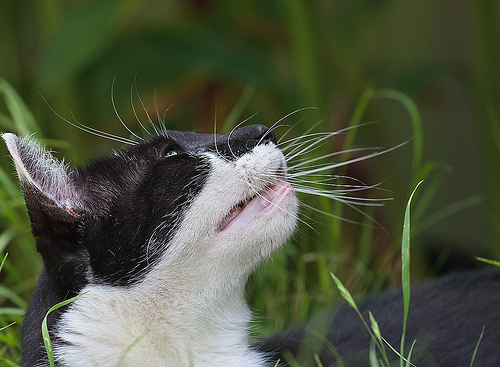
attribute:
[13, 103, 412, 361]
cat — lying, looking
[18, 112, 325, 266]
cat fur — white 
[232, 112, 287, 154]
nose — black 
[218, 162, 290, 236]
mouth — pink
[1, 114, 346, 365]
cat — looking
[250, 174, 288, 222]
lips — pink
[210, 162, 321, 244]
mouth — open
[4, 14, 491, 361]
grass — tall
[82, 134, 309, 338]
cat — white 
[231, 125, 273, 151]
cat nose — black 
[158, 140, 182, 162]
eye — cat's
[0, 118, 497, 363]
cat — black, white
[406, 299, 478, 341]
fur — black 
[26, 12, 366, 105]
background — out-of-focus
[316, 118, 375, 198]
whiskers cat — white 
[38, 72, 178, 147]
long hairs — white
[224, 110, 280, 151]
nose — black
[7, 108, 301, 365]
cat — black, white, looking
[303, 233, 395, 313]
grass — upright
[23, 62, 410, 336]
cat — white